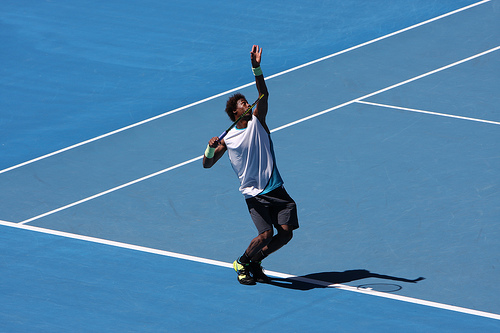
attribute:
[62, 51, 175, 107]
floor — blue 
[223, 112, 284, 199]
vest — white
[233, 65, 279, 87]
wrist band — small, rectangular, cloth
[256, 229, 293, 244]
knees — bent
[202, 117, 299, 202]
vest — white 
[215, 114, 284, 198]
jersey — white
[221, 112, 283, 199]
white shirt — cut off sleeve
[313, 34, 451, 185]
ground — blue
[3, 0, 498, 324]
markings — white 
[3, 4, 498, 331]
blue ground — blue 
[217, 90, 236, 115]
hair — black, puffy, curly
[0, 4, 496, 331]
pitch — blue 